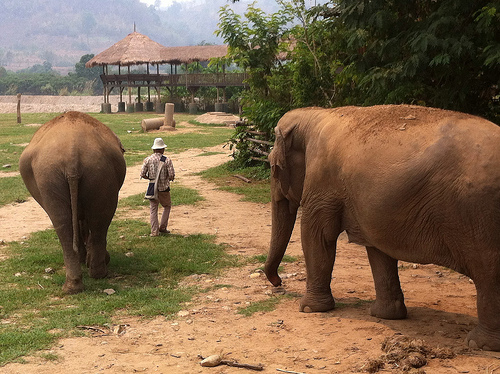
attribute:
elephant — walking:
[14, 105, 132, 296]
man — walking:
[136, 132, 179, 236]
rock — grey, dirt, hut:
[244, 259, 262, 286]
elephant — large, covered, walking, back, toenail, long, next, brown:
[227, 83, 492, 334]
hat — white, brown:
[151, 132, 170, 156]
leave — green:
[278, 37, 345, 73]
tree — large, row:
[220, 6, 297, 139]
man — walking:
[125, 130, 179, 250]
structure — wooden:
[151, 87, 184, 140]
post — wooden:
[157, 93, 182, 134]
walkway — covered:
[185, 145, 252, 276]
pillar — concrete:
[157, 85, 177, 125]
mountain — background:
[36, 6, 203, 76]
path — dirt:
[191, 105, 259, 219]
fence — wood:
[31, 82, 130, 117]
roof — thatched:
[107, 27, 168, 62]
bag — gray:
[137, 164, 166, 197]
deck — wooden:
[106, 67, 179, 96]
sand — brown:
[198, 145, 216, 182]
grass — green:
[128, 117, 148, 130]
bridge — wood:
[182, 71, 246, 99]